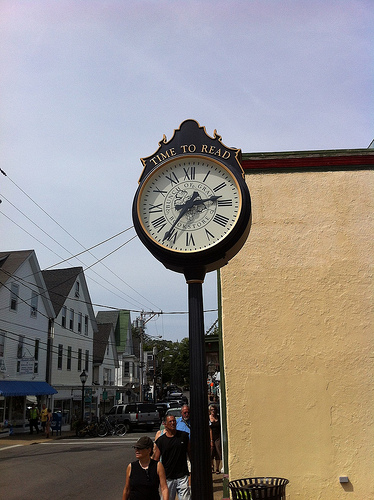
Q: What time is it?
A: 2:36.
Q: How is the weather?
A: Cloudy.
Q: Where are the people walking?
A: On the sidewalk.